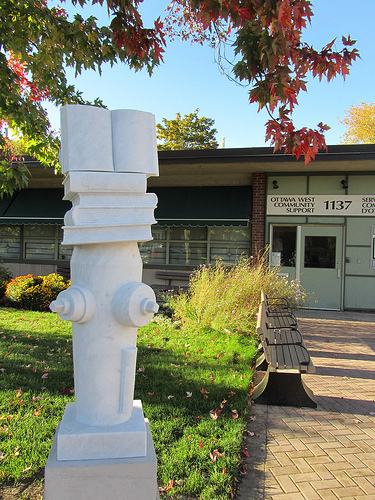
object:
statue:
[44, 104, 162, 499]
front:
[9, 284, 372, 499]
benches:
[251, 289, 317, 407]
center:
[2, 157, 372, 312]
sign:
[268, 195, 374, 215]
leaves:
[266, 21, 291, 54]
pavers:
[266, 410, 373, 496]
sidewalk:
[266, 308, 370, 498]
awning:
[8, 186, 250, 225]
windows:
[22, 223, 59, 257]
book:
[60, 106, 162, 173]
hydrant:
[51, 245, 154, 423]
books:
[62, 172, 149, 198]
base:
[45, 398, 158, 499]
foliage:
[285, 128, 309, 148]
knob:
[138, 299, 161, 319]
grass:
[160, 326, 232, 409]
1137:
[323, 199, 354, 210]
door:
[297, 223, 344, 310]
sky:
[167, 49, 211, 106]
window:
[304, 235, 337, 269]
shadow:
[0, 328, 72, 392]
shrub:
[6, 273, 70, 311]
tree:
[156, 110, 219, 152]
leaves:
[27, 331, 73, 399]